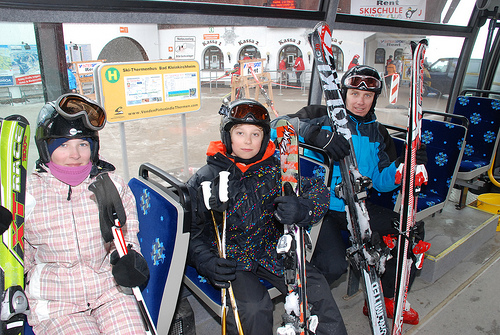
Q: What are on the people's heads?
A: Helmets.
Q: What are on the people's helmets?
A: Goggles.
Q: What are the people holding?
A: Skis and ski poles.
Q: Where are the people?
A: On a bus.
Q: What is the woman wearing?
A: A jacket.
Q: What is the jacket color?
A: Yellow, red, green and blue.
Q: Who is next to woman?
A: A man.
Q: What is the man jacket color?
A: Blue and black.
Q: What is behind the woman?
A: A window.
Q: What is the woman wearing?
A: A jacket.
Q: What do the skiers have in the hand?
A: Skies.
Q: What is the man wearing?
A: Blue ski gear.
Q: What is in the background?
A: A staging area for skiers.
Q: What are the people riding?
A: A bus.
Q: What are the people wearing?
A: Ski outfits.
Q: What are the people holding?
A: Skiing equipment.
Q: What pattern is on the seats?
A: A blue circular pattern.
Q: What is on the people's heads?
A: Goggles and helmets.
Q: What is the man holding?
A: Skiing equipment.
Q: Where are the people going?
A: To ski.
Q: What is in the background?
A: A white building.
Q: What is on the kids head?
A: Helmets.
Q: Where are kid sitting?
A: In a chair.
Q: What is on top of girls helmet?
A: Goggles are on helmet.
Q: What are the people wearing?
A: Snow gear.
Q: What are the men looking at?
A: Camera.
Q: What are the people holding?
A: Skis.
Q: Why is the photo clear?
A: Its during the day.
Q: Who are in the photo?
A: People.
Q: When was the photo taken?
A: Daytime.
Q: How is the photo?
A: Clear.